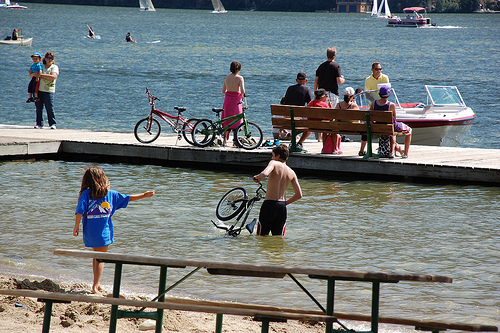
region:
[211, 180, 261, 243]
a bike in water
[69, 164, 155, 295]
a little girl in blue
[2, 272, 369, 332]
sand on the side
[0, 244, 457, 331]
a bench table in sand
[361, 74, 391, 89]
a yellow shirt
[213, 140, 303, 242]
a man in water with bike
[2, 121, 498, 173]
the long dock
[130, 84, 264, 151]
two bikes on the dock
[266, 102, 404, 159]
a wooden bench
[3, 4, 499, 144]
the blue water lake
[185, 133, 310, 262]
The boy is holding a bike.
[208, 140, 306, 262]
The bike is in the water.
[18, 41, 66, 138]
The woman is holding a little boy.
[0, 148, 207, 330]
The girl is standing by the water.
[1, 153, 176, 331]
The girl is standing on the sand.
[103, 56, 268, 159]
The bikes are on the dock.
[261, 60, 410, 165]
The bench is full.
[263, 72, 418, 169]
The bench is occupied,.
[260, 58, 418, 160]
Four people are sitting on the bench.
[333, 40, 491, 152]
The boat is on the water.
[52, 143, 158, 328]
a girl in the sand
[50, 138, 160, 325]
a girl in the water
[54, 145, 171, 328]
a girl near the water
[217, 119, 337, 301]
a man inside the water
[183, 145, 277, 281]
a cycle inside the water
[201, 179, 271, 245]
tire of the cycle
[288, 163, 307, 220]
hand of the man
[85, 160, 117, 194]
hairs of the girl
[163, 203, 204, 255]
riddles in the water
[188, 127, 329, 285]
a man with cycle in water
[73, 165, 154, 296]
Girl wearing a blue t-shirt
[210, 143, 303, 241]
Boy and his bicycle in the water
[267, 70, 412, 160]
Four people sitting on a bench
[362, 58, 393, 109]
Man in yellow driving a boat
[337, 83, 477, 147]
Small speedboat in the water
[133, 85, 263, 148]
Two bicycles on a dock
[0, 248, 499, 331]
Wood picnic table with metal legs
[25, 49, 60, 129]
Woman carrying a child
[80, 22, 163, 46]
Two people kayaking in the water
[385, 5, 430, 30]
White and red pontoon boat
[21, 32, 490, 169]
a group of people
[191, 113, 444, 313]
a man in the water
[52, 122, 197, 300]
a little girl in sand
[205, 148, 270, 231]
wheel of the cycle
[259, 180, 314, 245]
a man wearing pant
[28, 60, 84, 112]
a woman wearing shirt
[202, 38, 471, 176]
a group of people sitting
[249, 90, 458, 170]
a bench near water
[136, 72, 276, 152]
two cycles near water